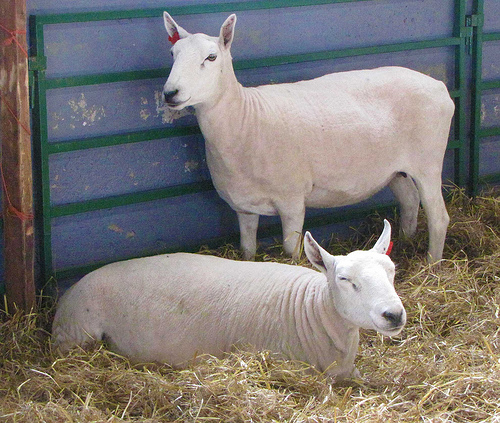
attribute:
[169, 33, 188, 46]
tag — red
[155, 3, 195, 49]
ear — white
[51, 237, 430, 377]
sheep — sleeping, white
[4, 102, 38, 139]
thread — red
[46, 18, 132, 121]
railings — green